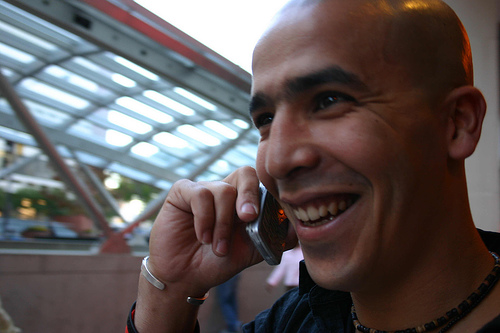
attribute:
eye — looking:
[309, 85, 351, 117]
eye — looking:
[253, 107, 278, 128]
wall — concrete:
[0, 250, 123, 332]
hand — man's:
[143, 162, 298, 299]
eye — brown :
[306, 90, 358, 115]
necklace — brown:
[339, 255, 491, 331]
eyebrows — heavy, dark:
[291, 66, 373, 88]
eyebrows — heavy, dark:
[243, 87, 276, 107]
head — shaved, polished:
[249, 0, 484, 296]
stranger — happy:
[82, 4, 499, 330]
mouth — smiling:
[253, 172, 387, 259]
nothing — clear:
[184, 31, 216, 42]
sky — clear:
[0, 0, 293, 228]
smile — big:
[272, 181, 360, 243]